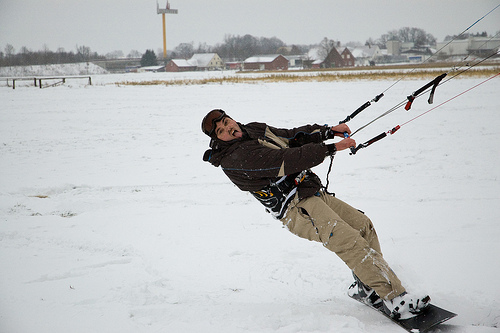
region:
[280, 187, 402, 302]
a pair of beige snow pants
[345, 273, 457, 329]
a black snowboard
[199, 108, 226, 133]
a pair of protective eyewear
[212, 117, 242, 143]
a man sticking his tongue out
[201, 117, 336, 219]
a brown winter coat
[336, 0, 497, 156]
a wire harness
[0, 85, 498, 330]
a snowy field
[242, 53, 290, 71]
a red building in distance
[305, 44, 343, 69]
a red house in distance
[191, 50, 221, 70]
a tan house in distance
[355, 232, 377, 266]
part of a troue=ser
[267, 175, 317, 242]
part of a pocket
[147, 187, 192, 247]
part of a snow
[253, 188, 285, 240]
part of a jacket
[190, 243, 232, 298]
part of a snow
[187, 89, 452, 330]
man leaning with snow board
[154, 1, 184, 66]
tall pole in the distance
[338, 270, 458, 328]
black snow board on feet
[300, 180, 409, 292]
tan pants on man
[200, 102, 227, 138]
goggles on mans head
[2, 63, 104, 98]
fence off in distance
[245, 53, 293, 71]
barn in a field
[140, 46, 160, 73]
pine tree in distance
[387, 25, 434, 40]
tree in the skyline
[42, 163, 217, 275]
snow on the ground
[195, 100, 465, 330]
Man is on a snowboard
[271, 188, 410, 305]
Man is wearing pants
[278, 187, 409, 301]
Man is wearing brown pants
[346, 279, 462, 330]
Man is on a black snowboard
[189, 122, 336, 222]
Man is wearing a jacket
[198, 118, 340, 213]
Man is wearing a brown jacket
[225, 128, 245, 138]
Man has his tongue out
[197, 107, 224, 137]
Man is wearing goggles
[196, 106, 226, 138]
Man is wearing brown goggles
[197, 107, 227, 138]
Man is wearing goggles on his forehead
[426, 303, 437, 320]
part of a board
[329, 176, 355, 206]
part of a pocket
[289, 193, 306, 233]
part of a pocket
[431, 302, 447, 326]
edge of a board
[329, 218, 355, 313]
poart of a knee